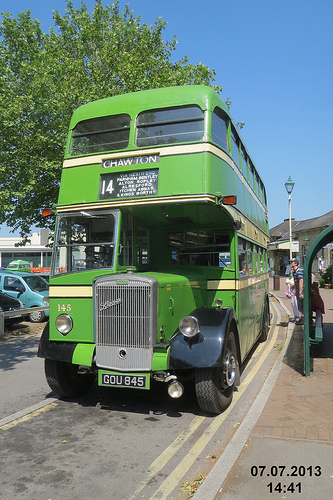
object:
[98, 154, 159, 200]
marquee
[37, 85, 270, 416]
bus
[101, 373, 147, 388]
license plate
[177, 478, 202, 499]
leaves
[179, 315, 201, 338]
headlight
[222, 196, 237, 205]
caution light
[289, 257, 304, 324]
man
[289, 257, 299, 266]
baseball cap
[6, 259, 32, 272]
van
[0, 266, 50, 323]
parking lot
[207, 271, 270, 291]
stripes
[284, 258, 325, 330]
people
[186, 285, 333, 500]
sidewalk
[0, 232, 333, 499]
street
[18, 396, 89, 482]
stains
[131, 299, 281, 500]
lines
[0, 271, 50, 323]
cars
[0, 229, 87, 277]
building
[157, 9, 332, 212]
sky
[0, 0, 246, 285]
trees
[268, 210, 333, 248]
roof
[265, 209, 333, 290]
building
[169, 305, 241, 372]
wheel cover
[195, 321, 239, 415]
tire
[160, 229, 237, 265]
window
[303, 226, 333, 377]
bus shelter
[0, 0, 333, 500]
photo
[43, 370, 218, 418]
shadow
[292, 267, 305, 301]
shirt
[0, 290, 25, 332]
car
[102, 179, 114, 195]
number 14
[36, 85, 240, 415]
front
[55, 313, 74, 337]
light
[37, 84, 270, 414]
double decker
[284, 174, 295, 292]
light post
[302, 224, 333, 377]
bus stop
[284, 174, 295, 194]
streetlamp